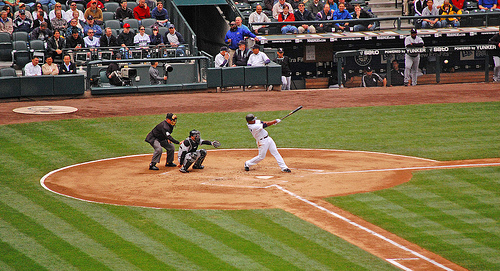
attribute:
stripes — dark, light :
[4, 106, 498, 268]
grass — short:
[7, 201, 331, 263]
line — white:
[388, 157, 435, 182]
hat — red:
[121, 20, 131, 32]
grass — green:
[1, 100, 499, 270]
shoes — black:
[233, 156, 293, 176]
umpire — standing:
[143, 110, 180, 175]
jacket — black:
[148, 120, 176, 145]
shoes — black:
[146, 157, 175, 173]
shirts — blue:
[235, 123, 285, 153]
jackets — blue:
[144, 111, 176, 148]